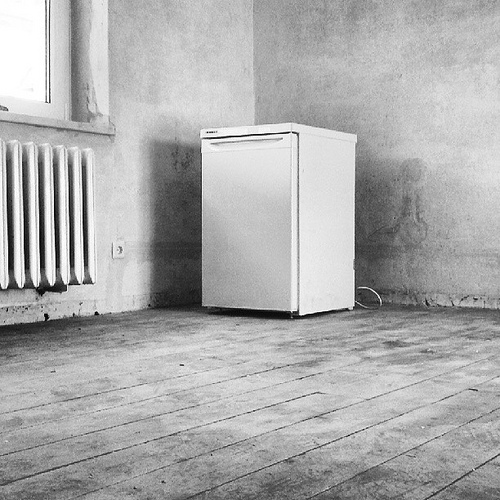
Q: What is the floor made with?
A: Wood.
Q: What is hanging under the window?
A: Radiator.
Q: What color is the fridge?
A: White.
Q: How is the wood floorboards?
A: Dirty.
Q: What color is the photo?
A: Black and white.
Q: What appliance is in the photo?
A: Small refrigerator.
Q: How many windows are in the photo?
A: 1.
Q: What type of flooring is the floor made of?
A: Hardwood.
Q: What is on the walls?
A: Nothing.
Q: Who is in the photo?
A: No one.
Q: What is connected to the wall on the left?
A: Radiator.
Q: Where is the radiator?
A: Under the window.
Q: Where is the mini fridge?
A: Corner of room.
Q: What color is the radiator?
A: White.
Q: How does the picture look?
A: Black and white.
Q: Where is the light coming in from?
A: Window.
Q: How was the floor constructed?
A: Wood.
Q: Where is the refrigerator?
A: Corner of room.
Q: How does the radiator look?
A: White.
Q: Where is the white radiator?
A: On wall.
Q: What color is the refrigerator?
A: White.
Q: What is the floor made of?
A: Wood.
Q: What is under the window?
A: A radiator.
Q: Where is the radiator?
A: Under the window.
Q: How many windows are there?
A: One.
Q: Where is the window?
A: Over the radiator.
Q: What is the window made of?
A: Glass.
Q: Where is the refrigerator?
A: On the floor.